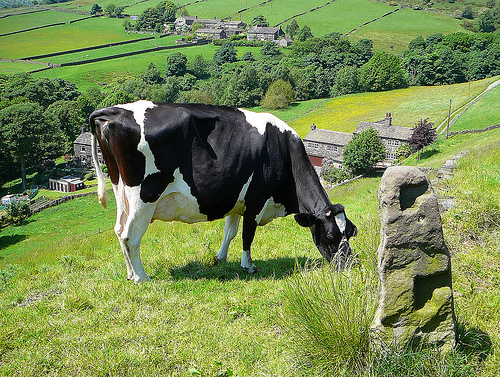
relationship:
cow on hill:
[80, 92, 361, 285] [7, 145, 499, 371]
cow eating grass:
[80, 92, 361, 285] [284, 249, 381, 360]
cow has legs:
[80, 92, 361, 285] [114, 202, 265, 278]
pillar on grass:
[372, 167, 469, 364] [284, 249, 381, 360]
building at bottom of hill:
[300, 109, 423, 176] [7, 145, 499, 371]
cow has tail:
[80, 92, 361, 285] [82, 112, 118, 208]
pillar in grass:
[372, 167, 469, 364] [284, 249, 381, 360]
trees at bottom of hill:
[1, 27, 497, 175] [7, 145, 499, 371]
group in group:
[161, 14, 292, 46] [101, 6, 354, 68]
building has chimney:
[300, 109, 423, 176] [384, 112, 401, 128]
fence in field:
[3, 54, 61, 72] [0, 6, 238, 89]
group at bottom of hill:
[161, 14, 292, 46] [7, 145, 499, 371]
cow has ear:
[80, 92, 361, 285] [287, 206, 322, 228]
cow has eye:
[80, 92, 361, 285] [321, 231, 337, 246]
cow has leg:
[80, 92, 361, 285] [123, 179, 158, 288]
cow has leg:
[80, 92, 361, 285] [239, 182, 264, 281]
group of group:
[101, 6, 354, 68] [161, 14, 292, 46]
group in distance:
[161, 14, 292, 46] [2, 1, 491, 92]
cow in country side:
[80, 92, 361, 285] [1, 2, 499, 377]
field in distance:
[0, 6, 238, 89] [2, 1, 491, 92]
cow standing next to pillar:
[80, 92, 361, 285] [372, 167, 469, 364]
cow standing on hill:
[80, 92, 361, 285] [7, 145, 499, 371]